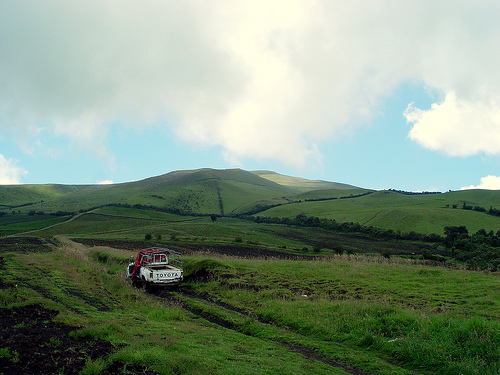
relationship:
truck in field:
[126, 248, 185, 293] [2, 248, 500, 375]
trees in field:
[258, 214, 500, 271] [2, 248, 500, 375]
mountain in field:
[122, 168, 371, 223] [2, 185, 499, 374]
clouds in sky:
[3, 0, 500, 161] [3, 0, 500, 194]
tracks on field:
[151, 284, 434, 375] [2, 248, 500, 375]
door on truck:
[130, 253, 143, 278] [126, 248, 185, 293]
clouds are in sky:
[3, 0, 500, 161] [3, 0, 500, 194]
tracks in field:
[151, 284, 434, 375] [2, 248, 500, 375]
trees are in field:
[258, 214, 500, 271] [2, 185, 499, 374]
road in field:
[1, 208, 98, 236] [2, 185, 499, 374]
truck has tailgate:
[126, 248, 185, 293] [150, 271, 181, 281]